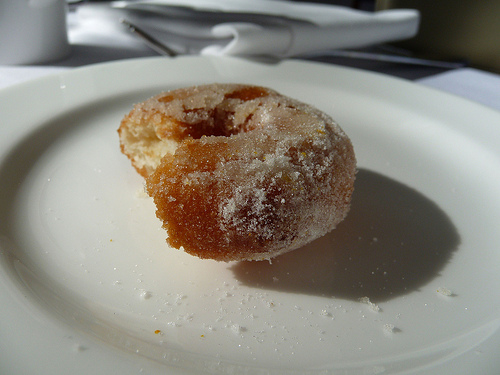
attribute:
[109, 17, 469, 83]
fork — long, silver, metal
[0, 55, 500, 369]
plate — large, round, white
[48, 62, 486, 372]
cup — small, round, white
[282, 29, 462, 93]
table — large, wide, white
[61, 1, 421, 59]
napkin — white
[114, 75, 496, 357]
plate table — white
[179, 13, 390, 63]
napkin — folded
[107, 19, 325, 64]
fork — silver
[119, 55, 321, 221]
donut — brown, round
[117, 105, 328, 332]
crumb — sugar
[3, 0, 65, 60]
cup — white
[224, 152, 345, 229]
sugar — powdered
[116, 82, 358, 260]
doughnut — small, round, half eaten